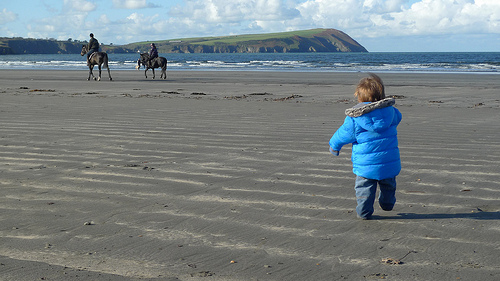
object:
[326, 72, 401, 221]
child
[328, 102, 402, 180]
jacket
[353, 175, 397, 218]
jeans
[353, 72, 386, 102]
hair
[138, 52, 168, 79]
horse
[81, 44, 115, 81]
horse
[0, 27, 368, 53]
hill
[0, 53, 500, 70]
water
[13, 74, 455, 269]
sand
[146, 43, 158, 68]
man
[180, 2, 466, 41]
sky